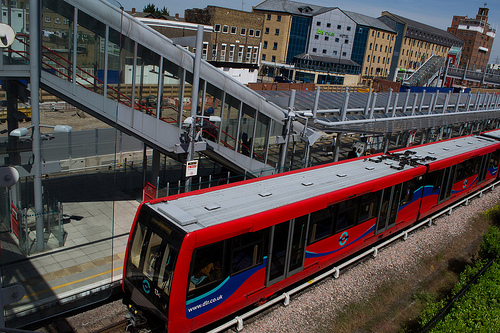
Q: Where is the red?
A: Train.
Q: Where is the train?
A: Station.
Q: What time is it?
A: Afternoon.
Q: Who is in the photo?
A: No people.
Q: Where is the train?
A: On the tracks.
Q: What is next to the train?
A: Rocks.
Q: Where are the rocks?
A: Next to train.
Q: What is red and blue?
A: Train.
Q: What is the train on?
A: Tracks.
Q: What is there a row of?
A: Buildings.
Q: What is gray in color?
A: Top of train.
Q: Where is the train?
A: On the track.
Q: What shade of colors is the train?
A: Red and blue.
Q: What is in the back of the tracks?
A: Tall buildings.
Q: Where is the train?
A: At the stain station.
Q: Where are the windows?
A: On the train.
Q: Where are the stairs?
A: By the train.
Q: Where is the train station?
A: In the city.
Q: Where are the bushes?
A: Next to the track.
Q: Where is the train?
A: Beside the platform.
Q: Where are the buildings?
A: Behind the train.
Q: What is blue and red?
A: The train.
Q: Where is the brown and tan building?
A: Next to the gray building.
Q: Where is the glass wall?
A: At the train platform.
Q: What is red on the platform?
A: The train.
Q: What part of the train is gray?
A: The top.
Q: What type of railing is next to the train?
A: Staircase.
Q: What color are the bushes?
A: Green.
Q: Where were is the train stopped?
A: Train stop.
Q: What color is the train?
A: Red.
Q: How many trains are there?
A: One.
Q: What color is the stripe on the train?
A: Blue.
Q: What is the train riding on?
A: Train tracks.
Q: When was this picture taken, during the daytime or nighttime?
A: Daytime.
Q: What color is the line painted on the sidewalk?
A: Yellow.